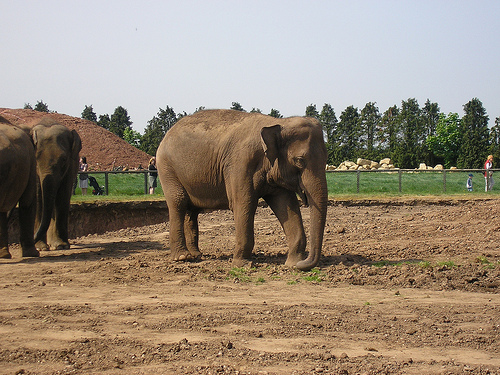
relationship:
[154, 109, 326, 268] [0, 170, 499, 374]
elephant standing on ground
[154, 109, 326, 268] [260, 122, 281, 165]
elephant has ear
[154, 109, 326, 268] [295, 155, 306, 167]
elephant has eye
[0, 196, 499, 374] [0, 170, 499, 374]
dirt on ground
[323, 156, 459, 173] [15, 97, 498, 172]
rocks sitting by trees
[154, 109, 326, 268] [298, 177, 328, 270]
elephant has trunk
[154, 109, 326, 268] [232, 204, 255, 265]
elephant has leg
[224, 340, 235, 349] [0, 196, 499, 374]
rock sitting in dirt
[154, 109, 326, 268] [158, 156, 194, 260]
elephant has leg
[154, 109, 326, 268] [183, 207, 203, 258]
elephant has leg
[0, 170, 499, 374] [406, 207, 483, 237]
ground has part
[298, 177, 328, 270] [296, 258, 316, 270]
trunk has part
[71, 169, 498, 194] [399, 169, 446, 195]
fence has part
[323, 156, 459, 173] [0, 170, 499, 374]
rocks on ground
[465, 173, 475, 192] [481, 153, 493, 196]
child standing with adult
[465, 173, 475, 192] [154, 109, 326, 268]
child watching elephant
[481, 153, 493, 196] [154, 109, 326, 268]
adult watching elephant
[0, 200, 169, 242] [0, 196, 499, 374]
mound made of dirt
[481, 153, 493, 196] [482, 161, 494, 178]
adult wearing jacket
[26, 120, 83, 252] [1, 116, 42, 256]
elephant standing by elephant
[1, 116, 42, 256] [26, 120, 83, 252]
elephant standing by elephant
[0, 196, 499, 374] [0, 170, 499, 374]
dirt sitting on ground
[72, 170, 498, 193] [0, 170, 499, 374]
grass growing on ground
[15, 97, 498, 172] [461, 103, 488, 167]
trees have leaves